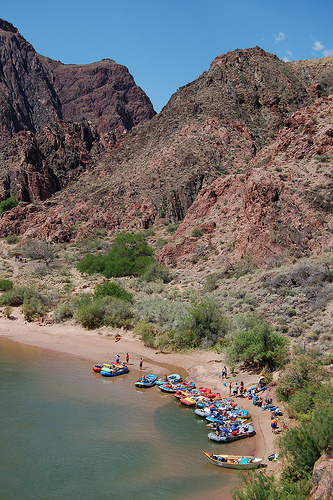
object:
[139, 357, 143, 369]
people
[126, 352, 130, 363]
people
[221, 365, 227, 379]
people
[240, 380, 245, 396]
people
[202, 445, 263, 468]
boat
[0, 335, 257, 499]
water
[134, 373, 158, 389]
boat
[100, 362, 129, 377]
boat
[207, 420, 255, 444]
boat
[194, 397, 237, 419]
boat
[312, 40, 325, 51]
clouds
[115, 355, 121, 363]
people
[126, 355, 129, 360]
shirt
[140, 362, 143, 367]
pants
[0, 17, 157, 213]
hills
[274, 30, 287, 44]
clouds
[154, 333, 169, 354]
tree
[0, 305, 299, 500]
riverbank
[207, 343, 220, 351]
grass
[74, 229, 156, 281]
trees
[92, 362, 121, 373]
boat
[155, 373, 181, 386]
raft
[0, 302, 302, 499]
sand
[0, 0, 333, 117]
sky